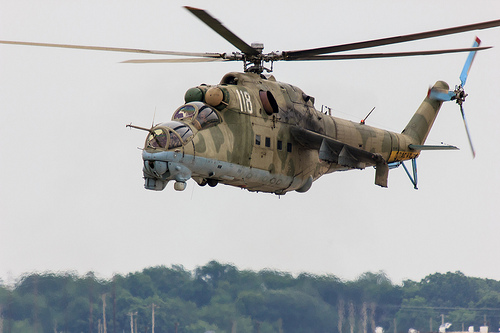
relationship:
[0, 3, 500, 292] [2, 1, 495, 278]
clouds are in air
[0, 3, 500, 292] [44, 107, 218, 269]
clouds are in sky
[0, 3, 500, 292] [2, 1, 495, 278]
clouds in air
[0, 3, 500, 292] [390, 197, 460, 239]
clouds in sky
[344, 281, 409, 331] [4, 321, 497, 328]
tree in ground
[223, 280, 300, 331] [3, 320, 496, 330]
tree in ground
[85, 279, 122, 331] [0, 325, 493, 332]
tree in ground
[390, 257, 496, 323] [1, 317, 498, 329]
tree in ground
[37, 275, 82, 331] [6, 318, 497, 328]
tree in ground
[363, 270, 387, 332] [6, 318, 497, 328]
tree in ground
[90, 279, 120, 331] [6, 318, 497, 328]
tree in ground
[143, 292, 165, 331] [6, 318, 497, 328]
tree in ground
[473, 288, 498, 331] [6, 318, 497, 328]
tree in ground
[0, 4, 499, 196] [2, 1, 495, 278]
army helicopter in air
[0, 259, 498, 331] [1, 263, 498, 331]
trees are in background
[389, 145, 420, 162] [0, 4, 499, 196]
yellow paint in back of army helicopter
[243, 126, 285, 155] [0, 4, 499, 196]
windows on side of army helicopter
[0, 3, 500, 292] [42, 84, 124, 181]
clouds in sky